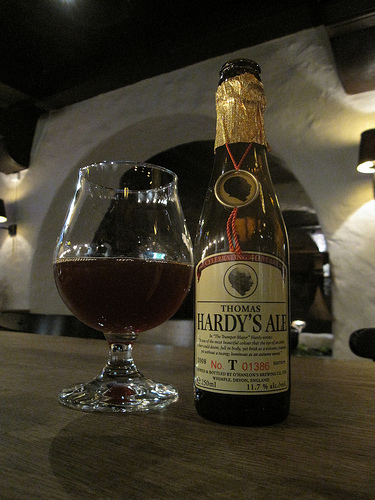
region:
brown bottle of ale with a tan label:
[193, 55, 293, 428]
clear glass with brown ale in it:
[53, 160, 191, 411]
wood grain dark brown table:
[2, 330, 367, 492]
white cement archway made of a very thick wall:
[29, 107, 341, 357]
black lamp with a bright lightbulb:
[358, 122, 372, 179]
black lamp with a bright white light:
[0, 196, 20, 243]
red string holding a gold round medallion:
[210, 101, 261, 261]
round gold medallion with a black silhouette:
[212, 164, 261, 209]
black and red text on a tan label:
[194, 248, 292, 398]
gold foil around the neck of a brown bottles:
[211, 74, 271, 153]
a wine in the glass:
[38, 141, 193, 434]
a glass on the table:
[50, 132, 208, 428]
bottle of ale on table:
[196, 54, 299, 424]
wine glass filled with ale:
[49, 161, 195, 418]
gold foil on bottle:
[216, 75, 267, 146]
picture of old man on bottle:
[226, 262, 257, 297]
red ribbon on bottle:
[224, 202, 244, 257]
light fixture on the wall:
[352, 124, 374, 178]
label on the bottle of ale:
[196, 254, 293, 391]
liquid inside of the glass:
[56, 261, 184, 329]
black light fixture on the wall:
[0, 192, 16, 244]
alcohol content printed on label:
[245, 381, 292, 392]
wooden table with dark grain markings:
[5, 350, 370, 494]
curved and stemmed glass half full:
[53, 156, 190, 406]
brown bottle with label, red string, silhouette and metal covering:
[191, 60, 284, 417]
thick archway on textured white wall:
[0, 20, 367, 336]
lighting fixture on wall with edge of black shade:
[0, 195, 15, 232]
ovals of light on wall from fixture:
[0, 165, 35, 285]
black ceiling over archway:
[0, 0, 369, 150]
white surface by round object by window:
[285, 200, 331, 353]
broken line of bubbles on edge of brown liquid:
[51, 255, 188, 263]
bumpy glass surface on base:
[55, 372, 175, 409]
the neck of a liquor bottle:
[208, 54, 274, 156]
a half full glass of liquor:
[49, 156, 195, 413]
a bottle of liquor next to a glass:
[54, 52, 298, 419]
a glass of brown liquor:
[59, 159, 188, 335]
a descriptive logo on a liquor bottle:
[193, 258, 289, 395]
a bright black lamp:
[0, 191, 19, 244]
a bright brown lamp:
[351, 127, 374, 191]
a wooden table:
[3, 420, 374, 499]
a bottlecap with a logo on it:
[210, 170, 260, 206]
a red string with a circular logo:
[209, 140, 265, 252]